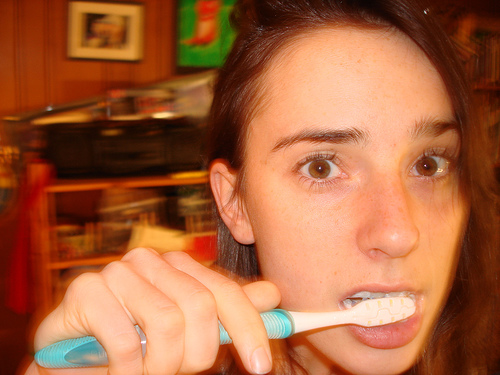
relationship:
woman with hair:
[35, 0, 498, 374] [206, 1, 500, 374]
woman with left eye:
[35, 0, 498, 374] [410, 154, 459, 180]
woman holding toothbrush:
[35, 0, 498, 374] [32, 296, 418, 370]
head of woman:
[241, 26, 469, 373] [35, 0, 498, 374]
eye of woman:
[296, 157, 344, 180] [35, 0, 498, 374]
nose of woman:
[358, 157, 419, 258] [35, 0, 498, 374]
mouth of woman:
[340, 282, 426, 350] [35, 0, 498, 374]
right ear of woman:
[209, 160, 254, 244] [35, 0, 498, 374]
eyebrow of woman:
[272, 128, 369, 154] [35, 0, 498, 374]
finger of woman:
[73, 272, 145, 375] [35, 0, 498, 374]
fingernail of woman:
[248, 348, 274, 374] [35, 0, 498, 374]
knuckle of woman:
[121, 247, 163, 266] [35, 0, 498, 374]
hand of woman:
[34, 248, 281, 374] [35, 0, 498, 374]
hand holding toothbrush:
[34, 248, 281, 374] [32, 296, 418, 370]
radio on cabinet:
[46, 117, 206, 176] [26, 165, 217, 355]